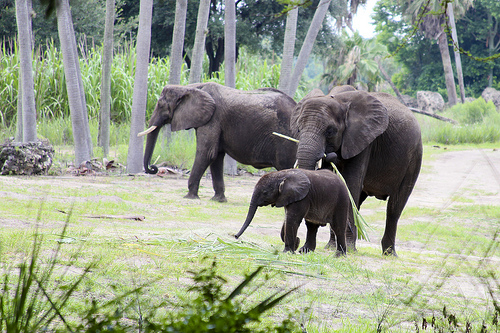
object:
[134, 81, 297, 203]
adults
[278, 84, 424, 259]
adults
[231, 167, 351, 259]
baby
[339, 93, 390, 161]
ear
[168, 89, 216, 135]
ear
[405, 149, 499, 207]
dirt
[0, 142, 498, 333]
ground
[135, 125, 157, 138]
tusk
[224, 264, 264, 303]
bush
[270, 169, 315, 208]
ear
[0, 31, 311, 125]
bushes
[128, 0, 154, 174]
tree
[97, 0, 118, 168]
tree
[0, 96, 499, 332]
grass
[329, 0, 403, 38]
sky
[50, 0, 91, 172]
tree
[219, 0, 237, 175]
tree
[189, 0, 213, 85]
tree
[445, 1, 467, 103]
tree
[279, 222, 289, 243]
knee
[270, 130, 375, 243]
plant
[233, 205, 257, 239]
trunk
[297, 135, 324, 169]
trunk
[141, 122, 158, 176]
trunk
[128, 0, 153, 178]
tree stem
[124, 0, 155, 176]
stem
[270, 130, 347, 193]
stalk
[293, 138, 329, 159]
mouth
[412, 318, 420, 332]
branch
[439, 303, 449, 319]
branch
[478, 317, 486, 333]
bush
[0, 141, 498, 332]
field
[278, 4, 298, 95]
tree stem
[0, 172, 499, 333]
leaves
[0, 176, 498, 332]
plant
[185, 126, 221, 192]
leg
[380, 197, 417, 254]
leg